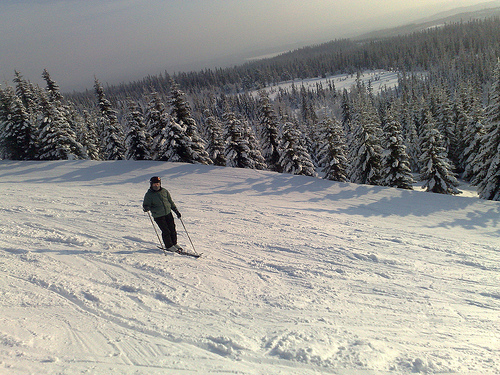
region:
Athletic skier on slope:
[137, 172, 201, 258]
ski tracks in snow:
[12, 261, 110, 318]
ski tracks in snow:
[17, 200, 68, 228]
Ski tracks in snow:
[224, 204, 294, 235]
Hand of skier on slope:
[174, 211, 184, 220]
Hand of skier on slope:
[139, 204, 150, 217]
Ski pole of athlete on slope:
[180, 219, 200, 253]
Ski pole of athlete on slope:
[146, 212, 163, 247]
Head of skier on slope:
[144, 176, 165, 188]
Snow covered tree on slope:
[315, 109, 351, 184]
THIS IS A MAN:
[139, 174, 182, 254]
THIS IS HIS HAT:
[148, 173, 164, 185]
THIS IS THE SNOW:
[1, 159, 498, 374]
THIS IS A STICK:
[180, 213, 200, 260]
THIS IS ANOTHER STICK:
[146, 208, 165, 255]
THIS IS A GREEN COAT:
[141, 188, 181, 221]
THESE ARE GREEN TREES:
[2, 13, 497, 198]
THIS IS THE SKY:
[0, 0, 497, 94]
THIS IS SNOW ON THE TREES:
[0, 68, 498, 199]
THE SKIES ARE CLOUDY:
[0, 0, 498, 95]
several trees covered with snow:
[43, 118, 458, 159]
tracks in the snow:
[331, 225, 458, 315]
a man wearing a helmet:
[137, 164, 182, 189]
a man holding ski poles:
[139, 171, 219, 274]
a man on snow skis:
[145, 183, 193, 268]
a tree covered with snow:
[377, 118, 409, 192]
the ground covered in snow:
[237, 200, 462, 332]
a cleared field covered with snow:
[240, 51, 433, 107]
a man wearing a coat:
[111, 180, 176, 228]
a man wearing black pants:
[145, 214, 177, 259]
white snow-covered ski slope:
[5, 163, 498, 373]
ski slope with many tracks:
[6, 165, 496, 372]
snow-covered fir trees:
[5, 35, 497, 200]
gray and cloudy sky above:
[2, 1, 498, 76]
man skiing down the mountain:
[142, 175, 199, 257]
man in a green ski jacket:
[142, 173, 200, 258]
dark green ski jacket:
[143, 187, 178, 218]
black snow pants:
[152, 214, 179, 249]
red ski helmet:
[148, 176, 160, 182]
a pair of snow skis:
[158, 244, 203, 258]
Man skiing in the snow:
[140, 170, 200, 255]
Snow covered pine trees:
[5, 70, 495, 190]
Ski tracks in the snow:
[0, 190, 490, 315]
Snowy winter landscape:
[8, 35, 497, 188]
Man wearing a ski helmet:
[140, 175, 195, 255]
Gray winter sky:
[0, 0, 430, 60]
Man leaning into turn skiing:
[140, 175, 195, 255]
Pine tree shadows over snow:
[225, 170, 490, 230]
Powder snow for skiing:
[0, 275, 490, 370]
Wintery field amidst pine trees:
[240, 75, 420, 95]